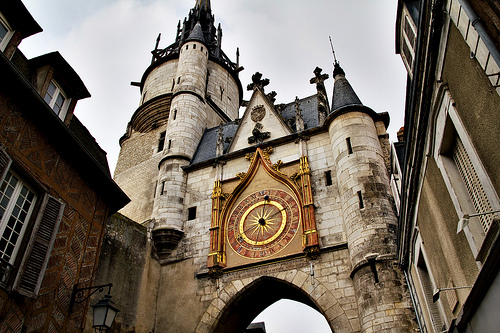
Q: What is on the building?
A: The clock.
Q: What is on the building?
A: The window.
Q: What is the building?
A: Stoley.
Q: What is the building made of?
A: Stone.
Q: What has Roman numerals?
A: The large clock.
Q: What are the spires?
A: On the castle.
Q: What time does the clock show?
A: 12:10.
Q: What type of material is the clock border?
A: Gold.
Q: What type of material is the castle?
A: Brick.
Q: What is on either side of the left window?
A: Shutters.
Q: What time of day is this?
A: Afternoon.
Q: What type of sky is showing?
A: Cloudy.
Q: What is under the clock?
A: Archway.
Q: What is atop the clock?
A: Cross.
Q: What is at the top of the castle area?
A: Tower.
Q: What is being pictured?
A: A medieval town gate.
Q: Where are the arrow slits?
A: In the walls.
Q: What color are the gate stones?
A: Grey.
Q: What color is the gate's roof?
A: Black.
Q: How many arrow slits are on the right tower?
A: Three.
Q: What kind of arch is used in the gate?
A: A pointed arch.